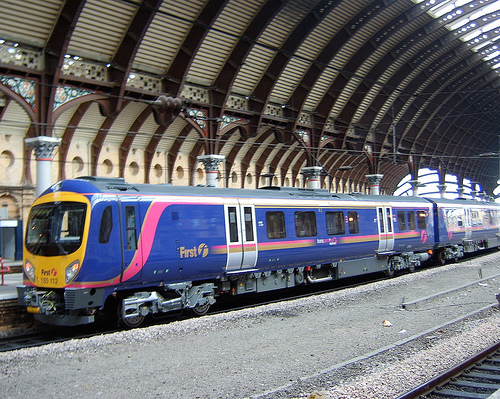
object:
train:
[16, 176, 499, 328]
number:
[55, 277, 60, 284]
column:
[23, 135, 65, 199]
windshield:
[24, 200, 88, 258]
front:
[16, 178, 98, 327]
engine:
[15, 175, 434, 327]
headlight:
[64, 258, 80, 283]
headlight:
[23, 257, 35, 283]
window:
[324, 211, 345, 236]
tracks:
[396, 341, 499, 397]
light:
[71, 262, 78, 271]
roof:
[71, 175, 430, 203]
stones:
[408, 365, 415, 371]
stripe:
[70, 201, 155, 284]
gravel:
[411, 361, 416, 363]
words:
[179, 245, 198, 259]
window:
[24, 200, 87, 256]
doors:
[240, 204, 257, 267]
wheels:
[189, 284, 212, 315]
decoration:
[25, 138, 62, 158]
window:
[294, 209, 318, 236]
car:
[423, 196, 499, 247]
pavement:
[0, 250, 497, 397]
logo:
[169, 220, 216, 273]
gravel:
[73, 347, 77, 351]